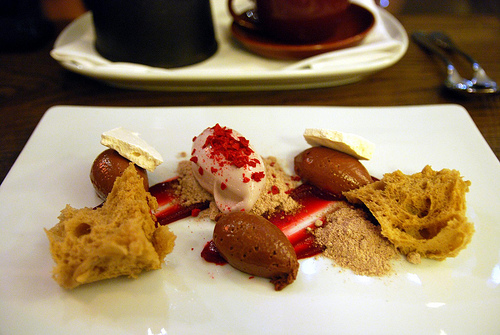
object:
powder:
[309, 203, 403, 275]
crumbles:
[266, 184, 281, 196]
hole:
[73, 220, 90, 238]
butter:
[97, 126, 163, 174]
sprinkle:
[186, 122, 265, 191]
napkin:
[51, 0, 399, 80]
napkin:
[306, 51, 401, 76]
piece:
[210, 209, 301, 292]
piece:
[188, 123, 266, 214]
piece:
[43, 163, 176, 292]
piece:
[289, 145, 372, 197]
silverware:
[429, 27, 499, 105]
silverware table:
[409, 27, 479, 99]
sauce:
[199, 183, 358, 266]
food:
[303, 127, 373, 162]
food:
[42, 160, 178, 290]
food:
[210, 210, 299, 292]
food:
[337, 165, 472, 263]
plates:
[49, 3, 409, 94]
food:
[291, 146, 374, 203]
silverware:
[406, 26, 489, 104]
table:
[0, 0, 499, 206]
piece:
[340, 163, 475, 259]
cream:
[187, 122, 266, 215]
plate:
[0, 105, 499, 334]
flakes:
[239, 171, 254, 185]